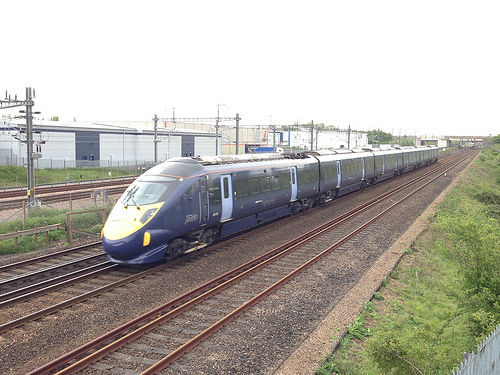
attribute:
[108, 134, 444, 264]
train — passenger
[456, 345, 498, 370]
fence — white